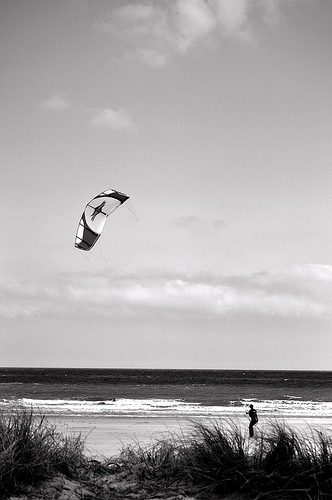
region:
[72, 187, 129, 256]
a black and white kiteboarding sail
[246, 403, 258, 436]
a man on the beach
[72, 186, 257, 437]
a kiteboarder heading out to sea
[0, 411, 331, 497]
a row of plants above the beach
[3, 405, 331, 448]
a sandy beach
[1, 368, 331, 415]
the ocean meeting a beach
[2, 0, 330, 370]
a gray cloudy day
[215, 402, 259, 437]
a man out on the beach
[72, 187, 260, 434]
a man going out kitesurfing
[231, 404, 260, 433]
a man on the beach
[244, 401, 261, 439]
black silhouette of a person flying a kite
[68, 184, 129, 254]
black and white kite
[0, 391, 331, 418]
small white capped waves lapping the shore line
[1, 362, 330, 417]
large expanse of ocean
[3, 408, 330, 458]
smooth sandy beach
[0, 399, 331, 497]
tall wispy sea grass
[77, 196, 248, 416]
thin white kite strings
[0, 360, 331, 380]
starkly contrasting horizon line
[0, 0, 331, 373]
slightly cloudy gray sky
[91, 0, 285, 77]
puffy transparent white cloud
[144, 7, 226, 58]
a cloud in the sky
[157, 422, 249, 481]
the grass is tall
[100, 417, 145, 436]
the sand on the beach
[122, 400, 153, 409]
the water is white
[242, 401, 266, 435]
a person standing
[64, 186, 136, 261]
a kite in the sky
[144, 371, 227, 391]
the water in the ocean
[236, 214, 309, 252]
the sky is clear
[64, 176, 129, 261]
the kite in the sky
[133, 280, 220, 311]
a white cloud in the sky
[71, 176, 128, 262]
big kite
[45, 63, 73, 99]
white clouds in blue sky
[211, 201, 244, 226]
white clouds in blue sky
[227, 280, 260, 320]
white clouds in blue sky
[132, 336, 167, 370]
white clouds in blue sky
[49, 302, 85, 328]
white clouds in blue sky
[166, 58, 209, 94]
white clouds in blue sky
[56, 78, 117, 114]
white clouds in blue sky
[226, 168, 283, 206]
white clouds in blue sky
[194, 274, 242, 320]
white clouds in blue sky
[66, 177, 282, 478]
he is at the beach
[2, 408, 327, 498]
tall grass in the sand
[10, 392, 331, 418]
white caps on the waves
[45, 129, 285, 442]
a para sail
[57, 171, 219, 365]
a white and black parachute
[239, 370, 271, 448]
the person is wearing black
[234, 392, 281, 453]
the person has a harness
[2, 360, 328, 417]
this is the ocean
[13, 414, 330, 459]
a sandy beach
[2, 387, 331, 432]
waves hitting the shore